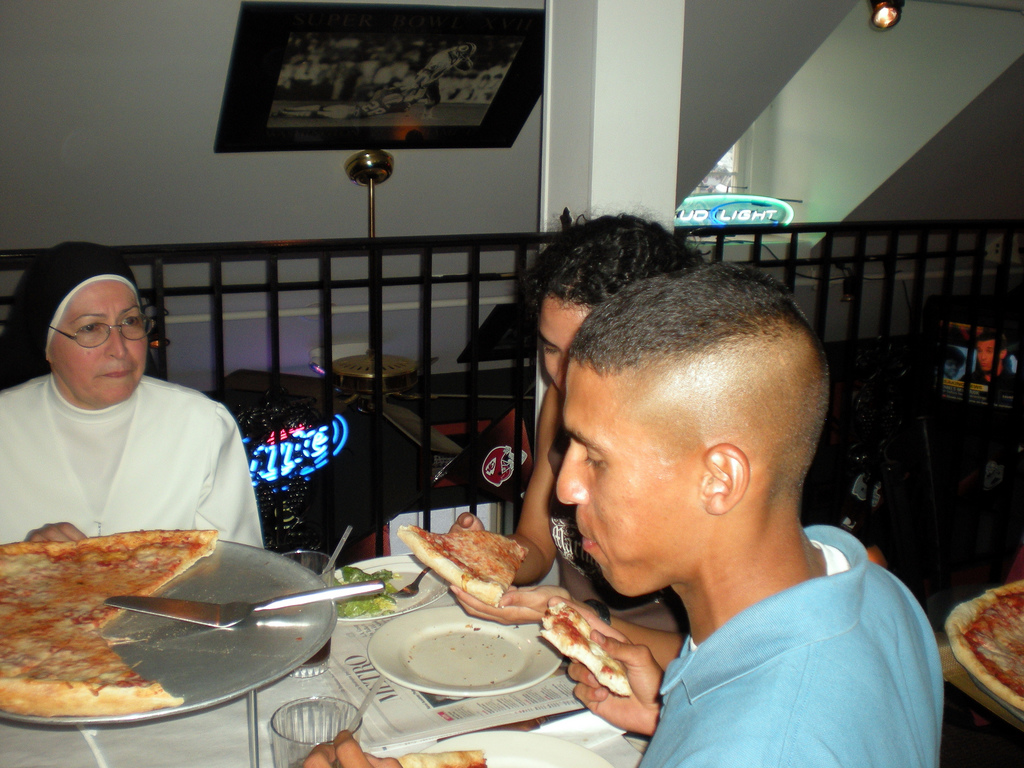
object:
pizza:
[540, 602, 633, 697]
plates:
[368, 606, 564, 698]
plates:
[334, 552, 451, 622]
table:
[0, 710, 589, 768]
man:
[556, 263, 945, 768]